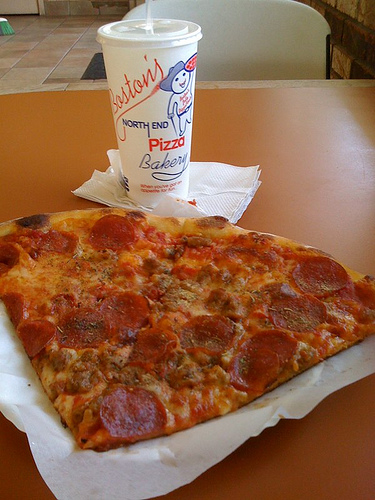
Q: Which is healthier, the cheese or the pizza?
A: The cheese is healthier than the pizza.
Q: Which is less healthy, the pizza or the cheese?
A: The pizza is less healthy than the cheese.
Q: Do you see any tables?
A: Yes, there is a table.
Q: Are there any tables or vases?
A: Yes, there is a table.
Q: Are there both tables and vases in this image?
A: No, there is a table but no vases.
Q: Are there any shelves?
A: No, there are no shelves.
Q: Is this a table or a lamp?
A: This is a table.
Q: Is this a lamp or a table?
A: This is a table.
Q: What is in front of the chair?
A: The table is in front of the chair.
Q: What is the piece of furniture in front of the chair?
A: The piece of furniture is a table.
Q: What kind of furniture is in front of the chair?
A: The piece of furniture is a table.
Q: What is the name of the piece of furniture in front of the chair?
A: The piece of furniture is a table.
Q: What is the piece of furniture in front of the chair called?
A: The piece of furniture is a table.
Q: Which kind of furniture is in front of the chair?
A: The piece of furniture is a table.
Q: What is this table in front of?
A: The table is in front of the chair.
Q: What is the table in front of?
A: The table is in front of the chair.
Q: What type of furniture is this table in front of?
A: The table is in front of the chair.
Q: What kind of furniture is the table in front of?
A: The table is in front of the chair.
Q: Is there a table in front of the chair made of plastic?
A: Yes, there is a table in front of the chair.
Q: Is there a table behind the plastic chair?
A: No, the table is in front of the chair.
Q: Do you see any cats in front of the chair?
A: No, there is a table in front of the chair.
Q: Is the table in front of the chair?
A: Yes, the table is in front of the chair.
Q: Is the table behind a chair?
A: No, the table is in front of a chair.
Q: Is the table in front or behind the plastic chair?
A: The table is in front of the chair.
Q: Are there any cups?
A: Yes, there is a cup.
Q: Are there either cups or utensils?
A: Yes, there is a cup.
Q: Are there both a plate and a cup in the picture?
A: No, there is a cup but no plates.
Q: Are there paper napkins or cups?
A: Yes, there is a paper cup.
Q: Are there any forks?
A: No, there are no forks.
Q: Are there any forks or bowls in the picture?
A: No, there are no forks or bowls.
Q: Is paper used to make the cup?
A: Yes, the cup is made of paper.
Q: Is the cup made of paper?
A: Yes, the cup is made of paper.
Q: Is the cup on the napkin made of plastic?
A: No, the cup is made of paper.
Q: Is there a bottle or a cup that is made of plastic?
A: No, there is a cup but it is made of paper.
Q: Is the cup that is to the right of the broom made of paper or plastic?
A: The cup is made of paper.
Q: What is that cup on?
A: The cup is on the napkin.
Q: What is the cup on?
A: The cup is on the napkin.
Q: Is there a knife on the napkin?
A: No, there is a cup on the napkin.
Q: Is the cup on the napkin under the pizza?
A: Yes, the cup is on the napkin.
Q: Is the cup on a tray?
A: No, the cup is on the napkin.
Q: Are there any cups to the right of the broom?
A: Yes, there is a cup to the right of the broom.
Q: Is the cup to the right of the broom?
A: Yes, the cup is to the right of the broom.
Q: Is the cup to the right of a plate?
A: No, the cup is to the right of the broom.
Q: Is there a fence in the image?
A: No, there are no fences.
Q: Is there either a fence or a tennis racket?
A: No, there are no fences or rackets.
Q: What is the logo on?
A: The logo is on the pizza.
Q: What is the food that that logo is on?
A: The food is a pizza.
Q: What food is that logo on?
A: The logo is on the pizza.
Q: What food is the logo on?
A: The logo is on the pizza.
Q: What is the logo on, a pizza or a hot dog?
A: The logo is on a pizza.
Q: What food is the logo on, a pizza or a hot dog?
A: The logo is on a pizza.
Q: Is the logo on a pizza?
A: Yes, the logo is on a pizza.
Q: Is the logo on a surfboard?
A: No, the logo is on a pizza.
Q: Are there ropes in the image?
A: No, there are no ropes.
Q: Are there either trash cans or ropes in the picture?
A: No, there are no ropes or trash cans.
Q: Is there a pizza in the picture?
A: Yes, there is a pizza.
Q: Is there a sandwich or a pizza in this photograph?
A: Yes, there is a pizza.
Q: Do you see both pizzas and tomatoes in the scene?
A: No, there is a pizza but no tomatoes.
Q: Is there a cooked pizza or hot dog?
A: Yes, there is a cooked pizza.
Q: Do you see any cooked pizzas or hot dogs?
A: Yes, there is a cooked pizza.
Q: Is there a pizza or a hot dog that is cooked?
A: Yes, the pizza is cooked.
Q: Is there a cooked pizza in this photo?
A: Yes, there is a cooked pizza.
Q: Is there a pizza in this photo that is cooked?
A: Yes, there is a pizza that is cooked.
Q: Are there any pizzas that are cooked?
A: Yes, there is a pizza that is cooked.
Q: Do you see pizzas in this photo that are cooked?
A: Yes, there is a pizza that is cooked.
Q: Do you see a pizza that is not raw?
A: Yes, there is a cooked pizza.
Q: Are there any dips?
A: No, there are no dips.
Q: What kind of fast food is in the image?
A: The fast food is a pizza.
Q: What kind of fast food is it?
A: The food is a pizza.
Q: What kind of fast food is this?
A: This is a pizza.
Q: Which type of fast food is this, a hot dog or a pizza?
A: This is a pizza.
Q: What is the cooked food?
A: The food is a pizza.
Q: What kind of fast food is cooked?
A: The fast food is a pizza.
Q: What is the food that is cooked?
A: The food is a pizza.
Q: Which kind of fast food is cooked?
A: The fast food is a pizza.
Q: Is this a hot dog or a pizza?
A: This is a pizza.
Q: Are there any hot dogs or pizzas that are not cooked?
A: No, there is a pizza but it is cooked.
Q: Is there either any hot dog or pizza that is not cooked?
A: No, there is a pizza but it is cooked.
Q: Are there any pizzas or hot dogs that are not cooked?
A: No, there is a pizza but it is cooked.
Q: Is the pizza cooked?
A: Yes, the pizza is cooked.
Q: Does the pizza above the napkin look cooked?
A: Yes, the pizza is cooked.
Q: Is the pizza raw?
A: No, the pizza is cooked.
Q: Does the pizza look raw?
A: No, the pizza is cooked.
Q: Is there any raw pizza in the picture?
A: No, there is a pizza but it is cooked.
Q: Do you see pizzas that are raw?
A: No, there is a pizza but it is cooked.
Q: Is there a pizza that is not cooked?
A: No, there is a pizza but it is cooked.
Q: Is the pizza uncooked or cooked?
A: The pizza is cooked.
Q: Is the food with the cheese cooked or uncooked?
A: The pizza is cooked.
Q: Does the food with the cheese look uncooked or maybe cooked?
A: The pizza is cooked.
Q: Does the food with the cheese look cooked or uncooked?
A: The pizza is cooked.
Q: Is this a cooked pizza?
A: Yes, this is a cooked pizza.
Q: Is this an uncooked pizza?
A: No, this is a cooked pizza.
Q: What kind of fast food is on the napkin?
A: The food is a pizza.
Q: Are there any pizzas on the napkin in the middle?
A: Yes, there is a pizza on the napkin.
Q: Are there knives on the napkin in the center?
A: No, there is a pizza on the napkin.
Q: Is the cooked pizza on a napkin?
A: Yes, the pizza is on a napkin.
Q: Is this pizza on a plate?
A: No, the pizza is on a napkin.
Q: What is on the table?
A: The pizza is on the table.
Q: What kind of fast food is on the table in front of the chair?
A: The food is a pizza.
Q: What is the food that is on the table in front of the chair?
A: The food is a pizza.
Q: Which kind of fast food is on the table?
A: The food is a pizza.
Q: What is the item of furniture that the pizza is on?
A: The piece of furniture is a table.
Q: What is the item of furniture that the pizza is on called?
A: The piece of furniture is a table.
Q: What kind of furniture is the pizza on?
A: The pizza is on the table.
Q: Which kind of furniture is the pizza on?
A: The pizza is on the table.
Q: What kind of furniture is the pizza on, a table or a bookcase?
A: The pizza is on a table.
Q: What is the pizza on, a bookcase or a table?
A: The pizza is on a table.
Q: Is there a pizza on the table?
A: Yes, there is a pizza on the table.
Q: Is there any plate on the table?
A: No, there is a pizza on the table.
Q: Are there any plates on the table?
A: No, there is a pizza on the table.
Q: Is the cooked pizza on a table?
A: Yes, the pizza is on a table.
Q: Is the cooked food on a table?
A: Yes, the pizza is on a table.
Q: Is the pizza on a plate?
A: No, the pizza is on a table.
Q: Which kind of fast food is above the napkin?
A: The food is a pizza.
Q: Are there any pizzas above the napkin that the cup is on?
A: Yes, there is a pizza above the napkin.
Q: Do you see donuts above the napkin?
A: No, there is a pizza above the napkin.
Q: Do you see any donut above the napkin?
A: No, there is a pizza above the napkin.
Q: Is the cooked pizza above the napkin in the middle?
A: Yes, the pizza is above the napkin.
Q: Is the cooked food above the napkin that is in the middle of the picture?
A: Yes, the pizza is above the napkin.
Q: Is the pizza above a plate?
A: No, the pizza is above the napkin.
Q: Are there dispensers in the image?
A: No, there are no dispensers.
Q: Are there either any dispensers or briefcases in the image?
A: No, there are no dispensers or briefcases.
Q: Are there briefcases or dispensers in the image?
A: No, there are no dispensers or briefcases.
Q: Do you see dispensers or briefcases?
A: No, there are no dispensers or briefcases.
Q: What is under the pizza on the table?
A: The napkin is under the pizza.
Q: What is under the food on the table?
A: The napkin is under the pizza.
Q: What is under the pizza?
A: The napkin is under the pizza.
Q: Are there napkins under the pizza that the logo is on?
A: Yes, there is a napkin under the pizza.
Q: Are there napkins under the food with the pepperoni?
A: Yes, there is a napkin under the pizza.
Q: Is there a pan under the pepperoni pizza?
A: No, there is a napkin under the pizza.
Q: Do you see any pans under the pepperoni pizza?
A: No, there is a napkin under the pizza.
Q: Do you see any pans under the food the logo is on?
A: No, there is a napkin under the pizza.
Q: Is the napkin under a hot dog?
A: No, the napkin is under the pizza.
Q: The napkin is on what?
A: The napkin is on the pizza.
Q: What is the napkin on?
A: The napkin is on the pizza.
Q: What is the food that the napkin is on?
A: The food is a pizza.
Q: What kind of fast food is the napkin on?
A: The napkin is on the pizza.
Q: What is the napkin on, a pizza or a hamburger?
A: The napkin is on a pizza.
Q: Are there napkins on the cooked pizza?
A: Yes, there is a napkin on the pizza.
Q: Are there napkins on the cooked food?
A: Yes, there is a napkin on the pizza.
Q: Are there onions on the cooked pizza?
A: No, there is a napkin on the pizza.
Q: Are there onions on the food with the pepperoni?
A: No, there is a napkin on the pizza.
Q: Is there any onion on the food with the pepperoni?
A: No, there is a napkin on the pizza.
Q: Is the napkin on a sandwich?
A: No, the napkin is on a pizza.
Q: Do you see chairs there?
A: Yes, there is a chair.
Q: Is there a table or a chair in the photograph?
A: Yes, there is a chair.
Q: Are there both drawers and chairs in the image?
A: No, there is a chair but no drawers.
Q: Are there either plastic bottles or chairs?
A: Yes, there is a plastic chair.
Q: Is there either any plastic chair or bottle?
A: Yes, there is a plastic chair.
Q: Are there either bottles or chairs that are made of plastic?
A: Yes, the chair is made of plastic.